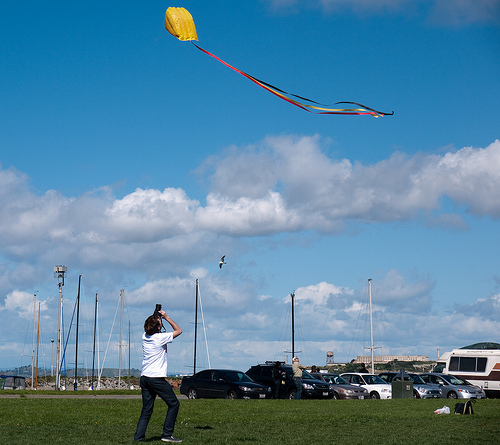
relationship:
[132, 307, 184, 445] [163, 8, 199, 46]
man photographing kite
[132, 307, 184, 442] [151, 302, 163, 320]
man holding camera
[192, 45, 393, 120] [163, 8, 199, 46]
tail of kite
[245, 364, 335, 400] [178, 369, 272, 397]
van parked beside car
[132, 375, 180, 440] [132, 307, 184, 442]
pants on man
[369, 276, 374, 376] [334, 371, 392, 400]
pole beside car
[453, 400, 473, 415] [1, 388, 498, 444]
bag on ground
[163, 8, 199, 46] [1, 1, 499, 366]
kite flying in sky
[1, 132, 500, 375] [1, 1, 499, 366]
clouds in sky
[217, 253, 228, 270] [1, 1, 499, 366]
bird in sky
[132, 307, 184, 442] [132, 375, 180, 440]
man wearing pants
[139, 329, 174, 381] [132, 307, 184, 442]
shirt on man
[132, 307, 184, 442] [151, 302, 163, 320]
man holding onto camera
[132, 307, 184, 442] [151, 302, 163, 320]
man holding up camera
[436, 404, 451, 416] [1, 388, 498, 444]
bag on ground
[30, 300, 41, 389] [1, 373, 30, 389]
mast of boat